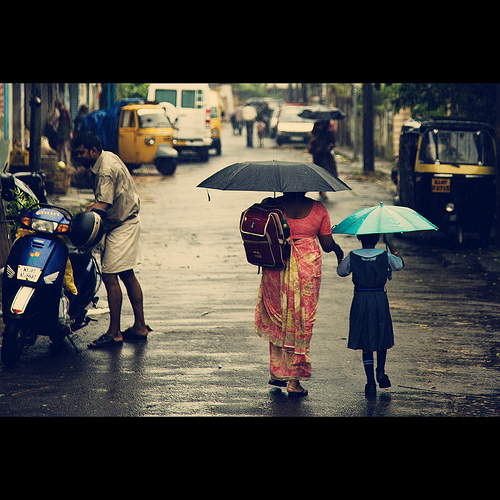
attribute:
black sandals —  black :
[90, 317, 170, 357]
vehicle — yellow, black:
[372, 126, 487, 218]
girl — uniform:
[335, 235, 404, 387]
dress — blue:
[340, 249, 395, 349]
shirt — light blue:
[331, 245, 402, 272]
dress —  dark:
[345, 245, 393, 357]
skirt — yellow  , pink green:
[253, 235, 322, 381]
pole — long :
[360, 80, 379, 173]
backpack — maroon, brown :
[235, 199, 294, 274]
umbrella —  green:
[330, 202, 439, 234]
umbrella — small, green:
[337, 203, 440, 236]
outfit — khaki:
[87, 147, 143, 274]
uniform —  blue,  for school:
[335, 245, 403, 354]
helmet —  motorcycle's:
[66, 209, 103, 250]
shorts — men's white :
[93, 207, 149, 286]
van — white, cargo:
[145, 84, 211, 161]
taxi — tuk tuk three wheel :
[391, 112, 498, 256]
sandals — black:
[89, 321, 148, 349]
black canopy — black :
[192, 158, 352, 195]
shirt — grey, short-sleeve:
[86, 150, 140, 224]